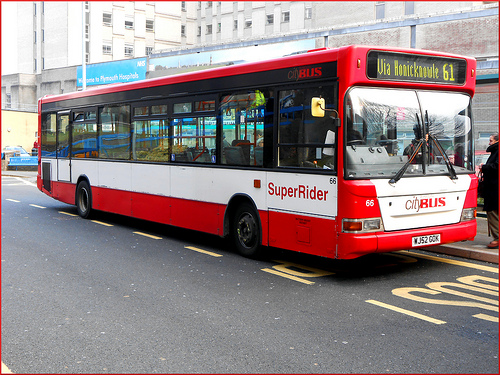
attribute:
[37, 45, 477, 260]
bus — colored, large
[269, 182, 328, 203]
printing — red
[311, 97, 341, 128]
mirror — big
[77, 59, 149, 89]
sign — colored, yellow, blue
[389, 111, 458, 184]
wipers — large, colored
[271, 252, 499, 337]
letters — yellow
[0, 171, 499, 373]
street — gray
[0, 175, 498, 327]
lines — yellow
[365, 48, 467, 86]
sign — yellow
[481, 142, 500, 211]
coat — black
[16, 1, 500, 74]
building — tall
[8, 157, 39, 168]
bench — blue